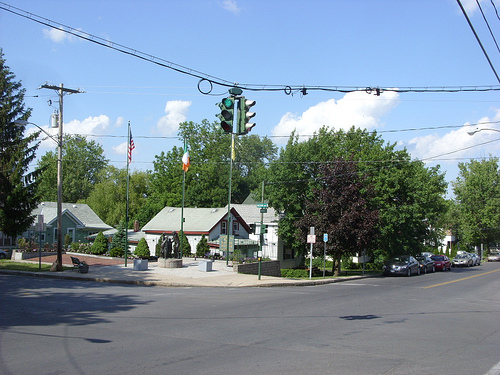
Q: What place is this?
A: It is a road.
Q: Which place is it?
A: It is a road.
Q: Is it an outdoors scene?
A: Yes, it is outdoors.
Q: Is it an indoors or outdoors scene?
A: It is outdoors.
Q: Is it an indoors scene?
A: No, it is outdoors.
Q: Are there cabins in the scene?
A: No, there are no cabins.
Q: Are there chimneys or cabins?
A: No, there are no cabins or chimneys.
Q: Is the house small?
A: Yes, the house is small.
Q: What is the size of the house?
A: The house is small.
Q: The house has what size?
A: The house is small.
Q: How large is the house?
A: The house is small.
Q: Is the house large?
A: No, the house is small.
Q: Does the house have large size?
A: No, the house is small.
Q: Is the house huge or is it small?
A: The house is small.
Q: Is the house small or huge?
A: The house is small.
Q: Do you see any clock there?
A: No, there are no clocks.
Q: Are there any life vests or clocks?
A: No, there are no clocks or life vests.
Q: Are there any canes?
A: No, there are no canes.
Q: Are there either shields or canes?
A: No, there are no canes or shields.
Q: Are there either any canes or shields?
A: No, there are no canes or shields.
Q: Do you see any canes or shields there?
A: No, there are no canes or shields.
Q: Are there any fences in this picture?
A: No, there are no fences.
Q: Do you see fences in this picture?
A: No, there are no fences.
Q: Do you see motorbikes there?
A: No, there are no motorbikes.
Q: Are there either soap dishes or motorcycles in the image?
A: No, there are no motorcycles or soap dishes.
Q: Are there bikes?
A: No, there are no bikes.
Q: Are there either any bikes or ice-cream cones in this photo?
A: No, there are no bikes or ice-cream cones.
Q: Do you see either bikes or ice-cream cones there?
A: No, there are no bikes or ice-cream cones.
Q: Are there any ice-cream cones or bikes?
A: No, there are no bikes or ice-cream cones.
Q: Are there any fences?
A: No, there are no fences.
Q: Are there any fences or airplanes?
A: No, there are no fences or airplanes.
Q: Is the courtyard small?
A: Yes, the courtyard is small.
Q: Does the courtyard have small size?
A: Yes, the courtyard is small.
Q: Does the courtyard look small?
A: Yes, the courtyard is small.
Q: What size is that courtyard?
A: The courtyard is small.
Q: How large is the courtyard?
A: The courtyard is small.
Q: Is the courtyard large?
A: No, the courtyard is small.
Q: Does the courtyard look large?
A: No, the courtyard is small.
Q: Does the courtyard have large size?
A: No, the courtyard is small.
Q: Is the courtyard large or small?
A: The courtyard is small.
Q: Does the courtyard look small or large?
A: The courtyard is small.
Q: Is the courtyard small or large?
A: The courtyard is small.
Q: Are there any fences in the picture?
A: No, there are no fences.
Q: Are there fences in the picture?
A: No, there are no fences.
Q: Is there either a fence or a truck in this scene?
A: No, there are no fences or trucks.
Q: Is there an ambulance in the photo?
A: No, there are no ambulances.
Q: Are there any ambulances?
A: No, there are no ambulances.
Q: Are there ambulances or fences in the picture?
A: No, there are no ambulances or fences.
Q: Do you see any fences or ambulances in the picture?
A: No, there are no ambulances or fences.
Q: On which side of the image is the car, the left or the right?
A: The car is on the right of the image.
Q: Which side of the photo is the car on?
A: The car is on the right of the image.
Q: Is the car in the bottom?
A: Yes, the car is in the bottom of the image.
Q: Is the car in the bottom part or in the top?
A: The car is in the bottom of the image.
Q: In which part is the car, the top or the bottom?
A: The car is in the bottom of the image.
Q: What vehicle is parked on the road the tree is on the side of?
A: The vehicle is a car.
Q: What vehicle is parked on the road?
A: The vehicle is a car.